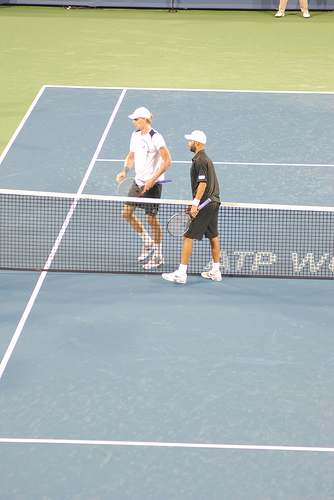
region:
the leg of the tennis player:
[119, 180, 153, 258]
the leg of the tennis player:
[142, 186, 164, 267]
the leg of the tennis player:
[176, 202, 204, 276]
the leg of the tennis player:
[207, 200, 219, 270]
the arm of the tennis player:
[149, 135, 171, 183]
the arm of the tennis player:
[195, 159, 209, 205]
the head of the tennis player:
[132, 107, 149, 132]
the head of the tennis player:
[187, 129, 207, 153]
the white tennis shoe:
[161, 269, 185, 281]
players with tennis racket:
[108, 90, 227, 290]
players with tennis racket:
[105, 103, 232, 284]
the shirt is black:
[179, 152, 216, 215]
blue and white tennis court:
[1, 85, 333, 499]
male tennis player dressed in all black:
[161, 128, 223, 284]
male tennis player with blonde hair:
[115, 104, 174, 268]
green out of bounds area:
[1, 5, 333, 154]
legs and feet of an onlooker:
[273, 0, 311, 17]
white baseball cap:
[128, 106, 150, 120]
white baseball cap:
[184, 129, 206, 144]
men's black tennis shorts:
[118, 179, 161, 214]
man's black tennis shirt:
[191, 148, 219, 200]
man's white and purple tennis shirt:
[127, 124, 166, 186]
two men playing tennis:
[114, 106, 229, 282]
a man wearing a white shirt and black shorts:
[114, 106, 173, 271]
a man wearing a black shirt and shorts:
[162, 130, 229, 288]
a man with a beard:
[182, 128, 209, 168]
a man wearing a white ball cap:
[182, 128, 210, 158]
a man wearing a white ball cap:
[126, 102, 154, 134]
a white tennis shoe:
[159, 269, 190, 284]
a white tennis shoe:
[199, 269, 223, 282]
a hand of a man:
[189, 205, 200, 218]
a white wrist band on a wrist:
[190, 197, 201, 207]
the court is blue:
[53, 106, 247, 343]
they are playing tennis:
[87, 114, 235, 285]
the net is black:
[2, 181, 332, 302]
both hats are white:
[122, 96, 231, 154]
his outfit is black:
[186, 147, 236, 237]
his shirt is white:
[124, 131, 165, 179]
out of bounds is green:
[13, 11, 282, 82]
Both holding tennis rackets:
[117, 161, 213, 252]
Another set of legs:
[279, 0, 330, 57]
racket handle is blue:
[157, 175, 180, 190]